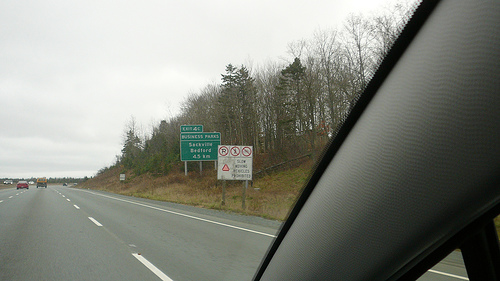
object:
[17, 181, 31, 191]
vehicle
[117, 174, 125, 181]
sign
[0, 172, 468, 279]
highway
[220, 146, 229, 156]
no parking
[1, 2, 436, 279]
windshield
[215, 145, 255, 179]
street sign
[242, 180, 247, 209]
post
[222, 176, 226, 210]
post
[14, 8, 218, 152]
clouds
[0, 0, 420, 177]
sky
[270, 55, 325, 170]
tree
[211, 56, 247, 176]
tree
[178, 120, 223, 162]
sign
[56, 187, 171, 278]
lines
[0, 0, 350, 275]
grasses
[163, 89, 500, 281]
vehicle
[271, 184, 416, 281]
part